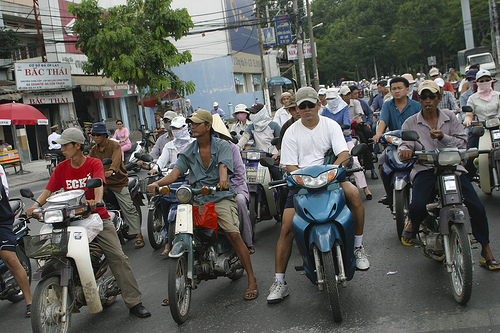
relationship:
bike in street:
[258, 143, 371, 323] [2, 104, 497, 326]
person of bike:
[264, 85, 370, 303] [258, 143, 371, 323]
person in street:
[264, 85, 370, 303] [2, 104, 497, 326]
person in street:
[397, 79, 499, 272] [2, 104, 497, 326]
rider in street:
[143, 109, 256, 309] [2, 104, 497, 326]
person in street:
[23, 127, 151, 319] [2, 104, 497, 326]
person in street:
[83, 122, 145, 250] [2, 104, 497, 326]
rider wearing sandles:
[145, 109, 257, 299] [157, 279, 261, 311]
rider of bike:
[145, 109, 257, 299] [139, 180, 241, 323]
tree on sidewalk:
[67, 2, 207, 119] [1, 130, 166, 189]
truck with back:
[454, 42, 496, 82] [456, 45, 481, 77]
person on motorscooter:
[264, 85, 370, 303] [259, 149, 369, 321]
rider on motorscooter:
[145, 109, 257, 299] [137, 182, 245, 322]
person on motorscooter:
[23, 127, 151, 319] [15, 173, 107, 331]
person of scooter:
[23, 127, 151, 319] [45, 195, 104, 291]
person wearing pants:
[23, 127, 151, 319] [89, 218, 139, 309]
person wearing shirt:
[23, 127, 151, 319] [45, 153, 110, 218]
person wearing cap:
[23, 127, 151, 319] [52, 127, 84, 146]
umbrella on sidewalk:
[0, 101, 48, 125] [2, 157, 49, 187]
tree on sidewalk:
[65, 4, 205, 127] [2, 151, 44, 183]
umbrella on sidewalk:
[0, 100, 47, 125] [0, 165, 494, 331]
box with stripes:
[1, 144, 26, 176] [0, 153, 19, 158]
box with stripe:
[1, 144, 26, 176] [0, 156, 19, 163]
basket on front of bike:
[25, 231, 85, 272] [12, 178, 106, 333]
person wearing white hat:
[468, 67, 499, 126] [473, 69, 488, 78]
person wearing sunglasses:
[468, 67, 499, 126] [476, 77, 491, 82]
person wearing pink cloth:
[468, 67, 499, 126] [473, 81, 495, 100]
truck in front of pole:
[454, 42, 496, 82] [454, 2, 479, 51]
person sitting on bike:
[27, 127, 151, 319] [12, 177, 127, 330]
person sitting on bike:
[264, 85, 379, 302] [242, 145, 371, 326]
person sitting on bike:
[395, 79, 497, 271] [386, 132, 496, 309]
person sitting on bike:
[83, 122, 146, 247] [104, 161, 148, 249]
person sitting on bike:
[232, 102, 277, 157] [239, 143, 289, 221]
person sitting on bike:
[386, 76, 414, 136] [371, 128, 420, 191]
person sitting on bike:
[112, 121, 129, 157] [393, 145, 488, 310]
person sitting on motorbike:
[23, 127, 151, 319] [276, 166, 376, 303]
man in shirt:
[380, 75, 422, 205] [378, 97, 419, 129]